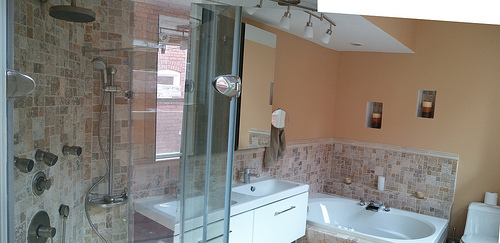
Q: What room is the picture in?
A: It is at the bathroom.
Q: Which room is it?
A: It is a bathroom.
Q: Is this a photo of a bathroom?
A: Yes, it is showing a bathroom.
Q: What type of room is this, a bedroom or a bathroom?
A: It is a bathroom.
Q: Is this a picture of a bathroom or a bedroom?
A: It is showing a bathroom.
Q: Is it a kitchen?
A: No, it is a bathroom.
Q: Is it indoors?
A: Yes, it is indoors.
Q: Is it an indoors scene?
A: Yes, it is indoors.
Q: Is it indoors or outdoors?
A: It is indoors.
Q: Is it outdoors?
A: No, it is indoors.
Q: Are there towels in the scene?
A: Yes, there is a towel.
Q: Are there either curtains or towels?
A: Yes, there is a towel.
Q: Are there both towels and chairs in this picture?
A: No, there is a towel but no chairs.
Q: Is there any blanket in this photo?
A: No, there are no blankets.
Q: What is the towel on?
A: The towel is on the wall.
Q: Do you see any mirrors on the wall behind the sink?
A: No, there is a towel on the wall.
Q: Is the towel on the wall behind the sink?
A: Yes, the towel is on the wall.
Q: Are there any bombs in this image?
A: No, there are no bombs.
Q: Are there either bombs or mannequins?
A: No, there are no bombs or mannequins.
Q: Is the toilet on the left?
A: No, the toilet is on the right of the image.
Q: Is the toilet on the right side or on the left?
A: The toilet is on the right of the image.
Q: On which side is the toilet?
A: The toilet is on the right of the image.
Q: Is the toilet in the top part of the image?
A: No, the toilet is in the bottom of the image.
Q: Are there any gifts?
A: No, there are no gifts.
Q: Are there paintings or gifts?
A: No, there are no gifts or paintings.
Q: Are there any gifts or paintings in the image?
A: No, there are no gifts or paintings.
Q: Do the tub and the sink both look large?
A: Yes, both the tub and the sink are large.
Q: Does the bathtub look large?
A: Yes, the bathtub is large.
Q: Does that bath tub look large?
A: Yes, the bath tub is large.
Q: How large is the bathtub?
A: The bathtub is large.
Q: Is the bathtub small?
A: No, the bathtub is large.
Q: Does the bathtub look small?
A: No, the bathtub is large.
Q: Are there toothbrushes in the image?
A: No, there are no toothbrushes.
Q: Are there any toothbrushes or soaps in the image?
A: No, there are no toothbrushes or soaps.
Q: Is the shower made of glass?
A: Yes, the shower is made of glass.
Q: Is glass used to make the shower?
A: Yes, the shower is made of glass.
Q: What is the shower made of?
A: The shower is made of glass.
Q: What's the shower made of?
A: The shower is made of glass.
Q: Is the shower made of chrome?
A: No, the shower is made of glass.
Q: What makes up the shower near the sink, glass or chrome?
A: The shower is made of glass.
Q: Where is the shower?
A: The shower is in the bathroom.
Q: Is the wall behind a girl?
A: No, the wall is behind the sink.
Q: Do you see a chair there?
A: No, there are no chairs.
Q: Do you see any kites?
A: No, there are no kites.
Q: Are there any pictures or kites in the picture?
A: No, there are no kites or pictures.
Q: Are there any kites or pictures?
A: No, there are no kites or pictures.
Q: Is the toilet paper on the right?
A: Yes, the toilet paper is on the right of the image.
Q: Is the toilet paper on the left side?
A: No, the toilet paper is on the right of the image.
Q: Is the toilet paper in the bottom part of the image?
A: Yes, the toilet paper is in the bottom of the image.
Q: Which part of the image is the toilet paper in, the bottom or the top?
A: The toilet paper is in the bottom of the image.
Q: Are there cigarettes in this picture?
A: No, there are no cigarettes.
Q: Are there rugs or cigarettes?
A: No, there are no cigarettes or rugs.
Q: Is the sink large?
A: Yes, the sink is large.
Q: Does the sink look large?
A: Yes, the sink is large.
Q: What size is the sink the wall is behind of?
A: The sink is large.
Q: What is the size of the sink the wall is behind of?
A: The sink is large.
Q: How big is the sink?
A: The sink is large.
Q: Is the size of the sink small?
A: No, the sink is large.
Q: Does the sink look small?
A: No, the sink is large.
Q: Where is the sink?
A: The sink is in the bathroom.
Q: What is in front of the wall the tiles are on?
A: The sink is in front of the wall.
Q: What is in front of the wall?
A: The sink is in front of the wall.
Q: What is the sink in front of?
A: The sink is in front of the wall.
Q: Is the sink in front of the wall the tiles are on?
A: Yes, the sink is in front of the wall.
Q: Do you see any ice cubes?
A: No, there are no ice cubes.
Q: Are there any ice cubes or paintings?
A: No, there are no ice cubes or paintings.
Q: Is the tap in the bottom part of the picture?
A: Yes, the tap is in the bottom of the image.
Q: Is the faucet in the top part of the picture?
A: No, the faucet is in the bottom of the image.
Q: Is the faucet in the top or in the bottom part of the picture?
A: The faucet is in the bottom of the image.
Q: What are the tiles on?
A: The tiles are on the wall.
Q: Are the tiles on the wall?
A: Yes, the tiles are on the wall.